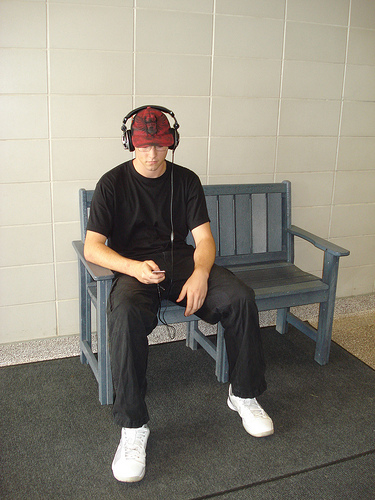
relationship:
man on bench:
[80, 104, 276, 484] [73, 180, 350, 408]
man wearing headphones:
[80, 104, 276, 484] [120, 104, 184, 149]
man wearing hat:
[80, 104, 276, 484] [131, 107, 176, 147]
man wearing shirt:
[80, 104, 276, 484] [84, 156, 214, 252]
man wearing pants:
[80, 104, 276, 484] [108, 250, 268, 425]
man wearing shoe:
[80, 104, 276, 484] [108, 421, 155, 485]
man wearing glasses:
[80, 104, 276, 484] [137, 147, 166, 155]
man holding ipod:
[80, 104, 276, 484] [154, 268, 166, 276]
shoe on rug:
[108, 421, 155, 485] [5, 320, 375, 499]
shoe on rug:
[223, 382, 279, 442] [5, 320, 375, 499]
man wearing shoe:
[80, 104, 276, 484] [223, 382, 279, 442]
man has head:
[80, 104, 276, 484] [128, 107, 173, 173]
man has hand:
[80, 104, 276, 484] [172, 274, 217, 317]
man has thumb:
[80, 104, 276, 484] [177, 284, 187, 305]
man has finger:
[80, 104, 276, 484] [192, 293, 198, 313]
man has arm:
[80, 104, 276, 484] [180, 217, 223, 276]